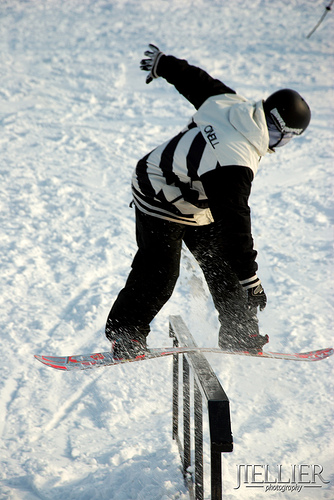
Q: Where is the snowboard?
A: Under the person.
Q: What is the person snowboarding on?
A: A black metal railing.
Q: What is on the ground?
A: White snow.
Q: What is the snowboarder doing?
A: Balancing on the rail.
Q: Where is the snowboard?
A: On a metal railing.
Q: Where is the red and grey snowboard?
A: On the black railing.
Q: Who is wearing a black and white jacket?
A: The snowboarder.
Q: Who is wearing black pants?
A: The snowboarder.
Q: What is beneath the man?
A: Snow.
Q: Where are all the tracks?
A: In the snow.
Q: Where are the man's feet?
A: On the snowboard.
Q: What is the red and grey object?
A: Snowboard.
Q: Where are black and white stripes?
A: On the man's jacket.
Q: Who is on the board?
A: A snowboarder.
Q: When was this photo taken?
A: Daylight hours.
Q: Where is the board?
A: On top of the railing.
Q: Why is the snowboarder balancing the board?
A: The snowboarder is performing a trick.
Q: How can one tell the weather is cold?
A: There is snow on the ground and the boarder is dressed warmly.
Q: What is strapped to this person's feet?
A: A snowboard.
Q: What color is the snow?
A: White.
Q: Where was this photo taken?
A: Outside, in the snow.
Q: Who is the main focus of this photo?
A: A snowboarder.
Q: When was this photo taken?
A: During the winter months.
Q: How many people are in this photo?
A: One.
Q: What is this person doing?
A: Snowboarding.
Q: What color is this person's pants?
A: Black.